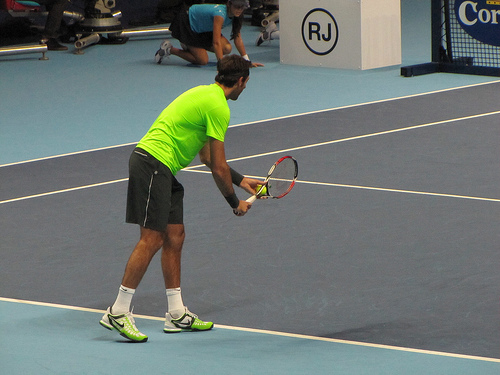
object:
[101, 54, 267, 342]
tennis player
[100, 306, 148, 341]
shoe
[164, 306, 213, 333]
shoe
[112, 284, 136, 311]
sock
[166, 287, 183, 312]
sock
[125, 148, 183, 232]
shorts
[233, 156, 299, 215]
tennis racket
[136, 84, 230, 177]
shirt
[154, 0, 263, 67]
ball girl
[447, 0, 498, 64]
net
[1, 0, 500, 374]
tennis court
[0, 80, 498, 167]
baseline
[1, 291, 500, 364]
baseline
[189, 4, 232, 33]
t-shirt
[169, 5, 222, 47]
skirt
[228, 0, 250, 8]
cap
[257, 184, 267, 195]
tennis ball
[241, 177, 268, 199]
hand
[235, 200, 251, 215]
hand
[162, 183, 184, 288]
leg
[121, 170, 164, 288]
leg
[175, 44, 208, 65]
leg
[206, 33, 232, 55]
leg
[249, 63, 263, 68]
hand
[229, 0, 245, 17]
head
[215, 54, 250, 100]
head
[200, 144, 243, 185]
arm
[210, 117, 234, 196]
arm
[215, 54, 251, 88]
hair